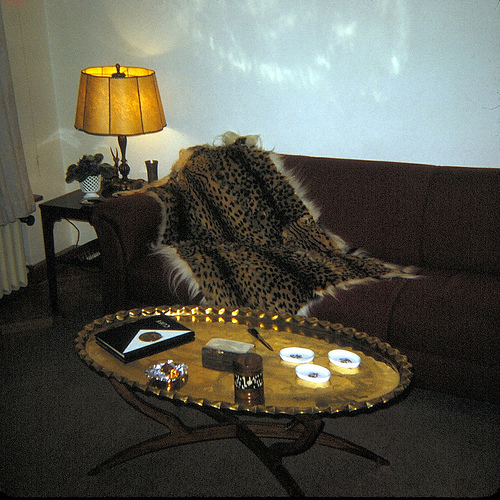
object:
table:
[73, 305, 415, 420]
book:
[88, 313, 197, 363]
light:
[70, 63, 168, 189]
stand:
[40, 212, 61, 328]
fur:
[135, 128, 421, 330]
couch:
[84, 142, 500, 397]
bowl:
[327, 347, 361, 368]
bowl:
[294, 362, 333, 383]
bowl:
[278, 345, 316, 365]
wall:
[36, 0, 500, 145]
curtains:
[0, 5, 41, 233]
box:
[200, 336, 258, 372]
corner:
[80, 0, 118, 56]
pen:
[246, 325, 274, 352]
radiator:
[0, 215, 30, 293]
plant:
[65, 153, 118, 186]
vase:
[79, 174, 102, 198]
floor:
[0, 334, 500, 500]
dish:
[146, 359, 189, 390]